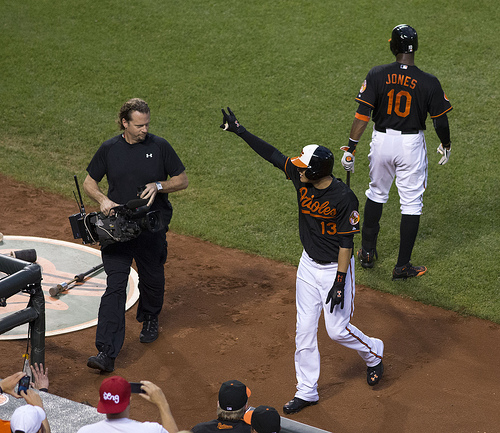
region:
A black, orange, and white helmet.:
[293, 145, 333, 182]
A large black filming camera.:
[67, 172, 166, 252]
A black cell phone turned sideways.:
[126, 384, 148, 394]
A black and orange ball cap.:
[217, 379, 251, 409]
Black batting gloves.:
[218, 107, 347, 312]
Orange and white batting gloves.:
[337, 143, 454, 173]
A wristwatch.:
[154, 182, 167, 194]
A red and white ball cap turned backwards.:
[97, 375, 130, 415]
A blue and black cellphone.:
[17, 375, 29, 397]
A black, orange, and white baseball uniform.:
[217, 113, 393, 415]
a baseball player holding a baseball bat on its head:
[343, 20, 453, 282]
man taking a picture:
[96, 378, 148, 415]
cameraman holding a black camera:
[67, 166, 169, 251]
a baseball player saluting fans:
[215, 107, 387, 407]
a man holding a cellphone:
[3, 370, 43, 409]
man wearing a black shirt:
[88, 134, 185, 229]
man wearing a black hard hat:
[388, 23, 420, 59]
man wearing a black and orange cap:
[216, 377, 252, 412]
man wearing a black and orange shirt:
[358, 60, 452, 123]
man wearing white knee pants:
[366, 128, 426, 213]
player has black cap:
[375, 27, 429, 68]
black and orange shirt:
[355, 70, 495, 136]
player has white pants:
[366, 138, 431, 210]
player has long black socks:
[360, 187, 421, 288]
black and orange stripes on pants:
[330, 290, 392, 370]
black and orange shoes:
[345, 242, 431, 297]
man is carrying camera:
[53, 157, 164, 287]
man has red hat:
[80, 370, 155, 427]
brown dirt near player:
[193, 258, 282, 419]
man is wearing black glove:
[212, 100, 286, 197]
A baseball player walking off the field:
[224, 108, 381, 404]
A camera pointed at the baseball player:
[70, 205, 146, 245]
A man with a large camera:
[81, 100, 187, 369]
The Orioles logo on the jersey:
[291, 183, 341, 220]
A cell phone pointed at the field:
[132, 382, 144, 392]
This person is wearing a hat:
[96, 376, 131, 413]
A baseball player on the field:
[367, 27, 451, 277]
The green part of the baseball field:
[146, 11, 343, 98]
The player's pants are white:
[293, 253, 385, 401]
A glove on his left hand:
[326, 268, 348, 308]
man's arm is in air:
[218, 83, 306, 193]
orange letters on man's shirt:
[293, 185, 354, 252]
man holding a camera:
[49, 152, 204, 259]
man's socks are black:
[360, 198, 425, 271]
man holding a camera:
[81, 360, 161, 425]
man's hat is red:
[86, 360, 141, 427]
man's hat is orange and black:
[202, 369, 264, 427]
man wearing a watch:
[143, 168, 172, 210]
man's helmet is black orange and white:
[290, 135, 332, 180]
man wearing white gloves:
[309, 135, 460, 192]